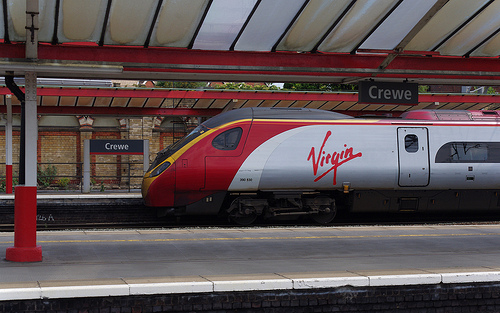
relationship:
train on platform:
[140, 105, 497, 223] [0, 187, 499, 312]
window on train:
[435, 140, 499, 163] [140, 105, 497, 223]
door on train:
[396, 124, 433, 189] [140, 105, 497, 223]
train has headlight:
[140, 105, 497, 223] [150, 159, 172, 179]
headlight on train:
[150, 159, 172, 179] [140, 105, 497, 223]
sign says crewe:
[90, 139, 140, 154] [103, 142, 129, 152]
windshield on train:
[167, 124, 207, 148] [140, 105, 497, 223]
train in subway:
[140, 105, 497, 223] [0, 1, 499, 228]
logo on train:
[306, 127, 365, 187] [140, 105, 497, 223]